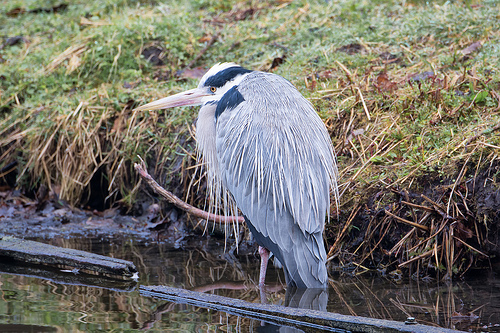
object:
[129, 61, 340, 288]
bird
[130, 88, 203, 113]
beak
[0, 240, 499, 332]
water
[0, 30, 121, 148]
grass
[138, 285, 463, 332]
stick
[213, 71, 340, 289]
wing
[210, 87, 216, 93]
eye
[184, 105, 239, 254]
feathers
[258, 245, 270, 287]
leg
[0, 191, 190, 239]
mud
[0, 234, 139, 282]
wood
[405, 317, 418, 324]
bolt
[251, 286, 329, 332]
board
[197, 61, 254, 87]
stripe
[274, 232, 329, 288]
tail